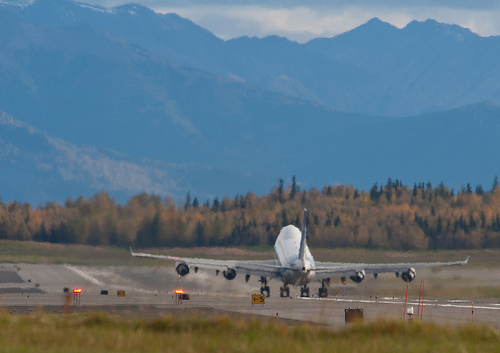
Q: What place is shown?
A: It is a forest.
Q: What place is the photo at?
A: It is at the forest.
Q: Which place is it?
A: It is a forest.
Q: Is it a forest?
A: Yes, it is a forest.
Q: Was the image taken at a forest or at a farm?
A: It was taken at a forest.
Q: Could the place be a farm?
A: No, it is a forest.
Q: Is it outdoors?
A: Yes, it is outdoors.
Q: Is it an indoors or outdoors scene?
A: It is outdoors.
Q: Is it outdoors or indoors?
A: It is outdoors.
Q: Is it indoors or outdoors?
A: It is outdoors.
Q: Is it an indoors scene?
A: No, it is outdoors.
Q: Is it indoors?
A: No, it is outdoors.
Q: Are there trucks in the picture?
A: No, there are no trucks.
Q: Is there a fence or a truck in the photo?
A: No, there are no trucks or fences.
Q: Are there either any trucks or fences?
A: No, there are no trucks or fences.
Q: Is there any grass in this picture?
A: Yes, there is grass.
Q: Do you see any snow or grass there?
A: Yes, there is grass.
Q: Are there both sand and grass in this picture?
A: No, there is grass but no sand.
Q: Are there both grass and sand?
A: No, there is grass but no sand.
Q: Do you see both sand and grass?
A: No, there is grass but no sand.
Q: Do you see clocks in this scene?
A: No, there are no clocks.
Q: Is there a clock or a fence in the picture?
A: No, there are no clocks or fences.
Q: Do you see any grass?
A: Yes, there is grass.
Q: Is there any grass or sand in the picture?
A: Yes, there is grass.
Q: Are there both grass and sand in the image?
A: No, there is grass but no sand.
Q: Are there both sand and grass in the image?
A: No, there is grass but no sand.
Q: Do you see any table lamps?
A: No, there are no table lamps.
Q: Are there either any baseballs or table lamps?
A: No, there are no table lamps or baseballs.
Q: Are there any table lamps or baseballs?
A: No, there are no table lamps or baseballs.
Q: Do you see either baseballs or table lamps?
A: No, there are no table lamps or baseballs.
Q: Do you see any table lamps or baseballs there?
A: No, there are no table lamps or baseballs.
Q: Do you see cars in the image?
A: No, there are no cars.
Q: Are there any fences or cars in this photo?
A: No, there are no cars or fences.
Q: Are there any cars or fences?
A: No, there are no cars or fences.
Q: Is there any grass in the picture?
A: Yes, there is grass.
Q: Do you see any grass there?
A: Yes, there is grass.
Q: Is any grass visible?
A: Yes, there is grass.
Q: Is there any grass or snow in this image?
A: Yes, there is grass.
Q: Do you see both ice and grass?
A: No, there is grass but no ice.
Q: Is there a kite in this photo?
A: No, there are no kites.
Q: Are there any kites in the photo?
A: No, there are no kites.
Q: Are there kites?
A: No, there are no kites.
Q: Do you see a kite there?
A: No, there are no kites.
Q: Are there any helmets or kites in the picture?
A: No, there are no kites or helmets.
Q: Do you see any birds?
A: No, there are no birds.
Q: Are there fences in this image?
A: No, there are no fences.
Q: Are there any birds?
A: No, there are no birds.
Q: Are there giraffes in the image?
A: No, there are no giraffes.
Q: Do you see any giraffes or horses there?
A: No, there are no giraffes or horses.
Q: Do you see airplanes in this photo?
A: Yes, there is an airplane.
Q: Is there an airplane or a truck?
A: Yes, there is an airplane.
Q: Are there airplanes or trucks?
A: Yes, there is an airplane.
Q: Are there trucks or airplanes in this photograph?
A: Yes, there is an airplane.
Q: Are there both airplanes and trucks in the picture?
A: No, there is an airplane but no trucks.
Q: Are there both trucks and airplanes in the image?
A: No, there is an airplane but no trucks.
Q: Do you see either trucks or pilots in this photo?
A: No, there are no trucks or pilots.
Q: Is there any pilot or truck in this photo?
A: No, there are no trucks or pilots.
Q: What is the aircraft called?
A: The aircraft is an airplane.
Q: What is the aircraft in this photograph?
A: The aircraft is an airplane.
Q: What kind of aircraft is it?
A: The aircraft is an airplane.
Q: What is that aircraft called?
A: That is an airplane.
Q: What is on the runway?
A: The airplane is on the runway.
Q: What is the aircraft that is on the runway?
A: The aircraft is an airplane.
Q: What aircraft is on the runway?
A: The aircraft is an airplane.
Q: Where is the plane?
A: The plane is on the runway.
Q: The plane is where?
A: The plane is on the runway.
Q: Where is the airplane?
A: The plane is on the runway.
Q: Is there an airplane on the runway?
A: Yes, there is an airplane on the runway.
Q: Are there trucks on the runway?
A: No, there is an airplane on the runway.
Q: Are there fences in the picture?
A: No, there are no fences.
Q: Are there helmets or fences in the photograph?
A: No, there are no fences or helmets.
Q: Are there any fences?
A: No, there are no fences.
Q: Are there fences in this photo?
A: No, there are no fences.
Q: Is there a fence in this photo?
A: No, there are no fences.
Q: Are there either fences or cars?
A: No, there are no fences or cars.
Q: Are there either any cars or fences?
A: No, there are no fences or cars.